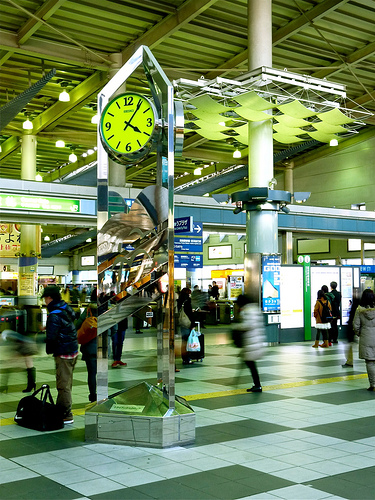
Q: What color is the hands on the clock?
A: Black.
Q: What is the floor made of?
A: Tiles.